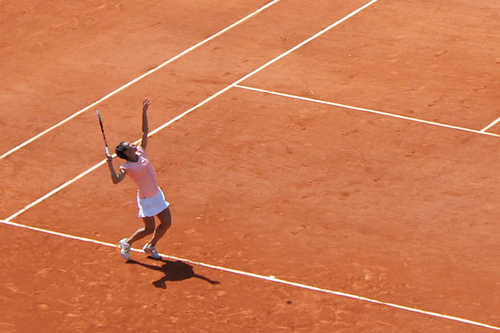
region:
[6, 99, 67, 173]
white line on court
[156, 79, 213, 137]
white line on court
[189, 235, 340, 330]
white line on court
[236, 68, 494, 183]
white line on court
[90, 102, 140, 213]
woman holding a racket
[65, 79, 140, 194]
woman holding a tennis racket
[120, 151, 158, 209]
woman wearing a pink shirt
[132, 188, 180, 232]
woman wearing a white skirt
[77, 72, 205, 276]
woman playing tennis in court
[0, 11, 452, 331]
woman standing on orange court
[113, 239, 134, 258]
shoe on the player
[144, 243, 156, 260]
shoe on the player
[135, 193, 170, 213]
skirt on the player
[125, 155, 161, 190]
shirt on the player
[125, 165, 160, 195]
pink shirt on the player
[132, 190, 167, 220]
white skirt on the player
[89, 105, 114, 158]
racquet in the player hand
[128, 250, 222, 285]
shadow on the ground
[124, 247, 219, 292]
player shadow on the ground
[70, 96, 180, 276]
girl playing tennis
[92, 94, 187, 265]
the tennis player prepareing to hit the ball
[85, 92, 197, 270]
the tennis player on the court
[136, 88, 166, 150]
the arm in the air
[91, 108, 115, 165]
the racquet in the hand of the tennis player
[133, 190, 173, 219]
the white skirt of the player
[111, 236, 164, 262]
the white shoes on the tennis player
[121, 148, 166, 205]
the pink shirt on the player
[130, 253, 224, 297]
the players shadow on the clay court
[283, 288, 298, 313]
the shadow of the ball in the air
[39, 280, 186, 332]
the feet prints in the clay tennis court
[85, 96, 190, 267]
Woman playing tennis.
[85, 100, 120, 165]
Tennis racquet in the hand.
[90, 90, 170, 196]
Pink shirt on the woman.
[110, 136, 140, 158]
black hair on the woman.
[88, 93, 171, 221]
white skirt on the woman.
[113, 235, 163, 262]
White shoes on the feet.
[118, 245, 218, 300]
shadow on the ground.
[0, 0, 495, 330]
clay colored tennis court.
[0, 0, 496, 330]
White lines on the tennis court.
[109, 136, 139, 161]
short hair on the woman.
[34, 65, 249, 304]
A woman playing tennis.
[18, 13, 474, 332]
White lines on a tennis court.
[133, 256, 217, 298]
Shadow of the tennis player.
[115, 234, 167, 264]
A pair of white tennis shoes.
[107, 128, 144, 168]
A woman with short black hair.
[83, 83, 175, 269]
Woman getting ready to get a tennis ball.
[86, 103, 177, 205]
Woman with tennis racquet in right hand.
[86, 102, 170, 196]
Woman wearing a pink shirt.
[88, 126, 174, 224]
Woman wearing a white tennis skirt.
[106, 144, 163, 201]
A pink short sleeve shirt.